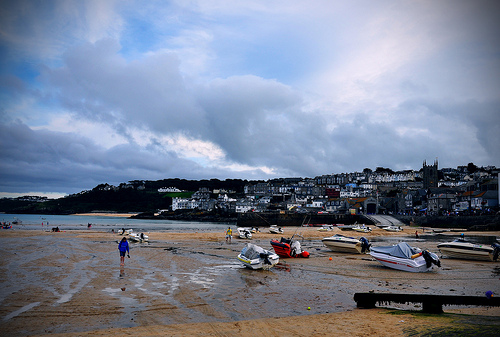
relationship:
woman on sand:
[118, 237, 130, 266] [8, 227, 496, 334]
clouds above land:
[2, 0, 497, 195] [0, 212, 497, 329]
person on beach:
[116, 236, 133, 271] [0, 225, 498, 335]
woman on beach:
[118, 236, 130, 265] [0, 225, 498, 335]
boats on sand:
[239, 239, 275, 280] [76, 276, 313, 333]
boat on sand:
[269, 238, 310, 259] [240, 309, 277, 322]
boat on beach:
[368, 242, 440, 273] [0, 222, 499, 335]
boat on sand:
[370, 237, 467, 278] [314, 267, 349, 292]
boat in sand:
[237, 237, 280, 269] [8, 227, 496, 334]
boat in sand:
[268, 235, 309, 257] [8, 227, 496, 334]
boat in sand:
[318, 232, 370, 252] [8, 227, 496, 334]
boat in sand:
[365, 242, 443, 268] [8, 227, 496, 334]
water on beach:
[3, 261, 306, 324] [3, 215, 497, 331]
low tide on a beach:
[16, 259, 91, 294] [4, 232, 114, 334]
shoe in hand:
[123, 254, 131, 260] [123, 252, 131, 260]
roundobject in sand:
[328, 255, 333, 262] [0, 227, 354, 334]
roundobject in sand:
[302, 300, 312, 311] [0, 227, 354, 334]